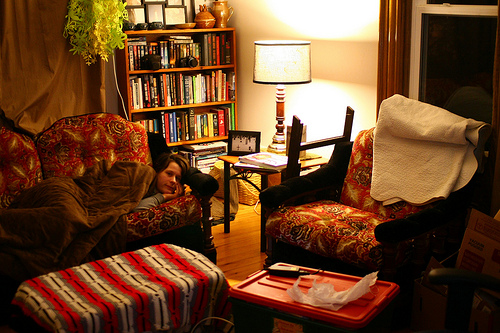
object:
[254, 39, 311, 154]
lamp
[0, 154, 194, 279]
woman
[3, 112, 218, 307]
couch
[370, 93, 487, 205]
blanket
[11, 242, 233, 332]
afghan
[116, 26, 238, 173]
bookcase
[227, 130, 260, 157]
frame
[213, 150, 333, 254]
table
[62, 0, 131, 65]
plant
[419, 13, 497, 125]
window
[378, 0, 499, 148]
frame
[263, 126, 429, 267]
cushion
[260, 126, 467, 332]
chair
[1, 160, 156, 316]
cover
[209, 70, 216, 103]
book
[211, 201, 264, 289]
floor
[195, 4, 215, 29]
pot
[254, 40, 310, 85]
lampshade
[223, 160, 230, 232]
leg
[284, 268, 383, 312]
paper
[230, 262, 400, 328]
lid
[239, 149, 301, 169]
magazine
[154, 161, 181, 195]
face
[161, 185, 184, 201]
hand